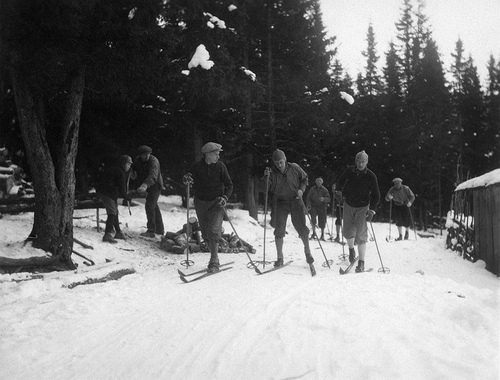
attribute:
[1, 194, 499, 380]
snow — snow-covered field, white, covering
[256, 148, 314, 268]
person — middle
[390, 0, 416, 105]
tree — tall, background, tall pine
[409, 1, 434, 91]
tree — tall, background, tall pine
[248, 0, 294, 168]
tree — tall, background, tall pine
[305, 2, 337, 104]
tree — tall, background, tall pine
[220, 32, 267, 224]
tree — tall, background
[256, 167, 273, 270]
ski pole — long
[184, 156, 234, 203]
sweater — black, dark v-neck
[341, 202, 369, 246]
shorts — tan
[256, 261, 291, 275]
ski — narrow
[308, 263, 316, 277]
ski — narrow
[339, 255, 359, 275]
ski — narrow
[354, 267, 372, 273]
ski — narrow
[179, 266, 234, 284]
ski — narrow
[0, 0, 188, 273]
tree — big, large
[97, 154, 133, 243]
person — tween age boy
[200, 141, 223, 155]
hat — gray, oversize newsboy hat, newsboy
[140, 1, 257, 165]
tree — tall pine, background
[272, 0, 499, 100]
sky — cloudy, background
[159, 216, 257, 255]
pile — of wood, of logs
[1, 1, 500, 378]
scene — monochrome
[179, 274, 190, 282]
tip — curled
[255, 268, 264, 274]
tip — curled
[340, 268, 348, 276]
tip — curled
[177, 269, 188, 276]
tip — curled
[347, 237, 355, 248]
sock — knit knee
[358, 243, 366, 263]
sock — knit knee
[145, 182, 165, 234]
pants — long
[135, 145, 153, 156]
cap — dark colored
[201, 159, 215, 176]
shirt — dark front-button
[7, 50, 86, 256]
tree trunk — thick